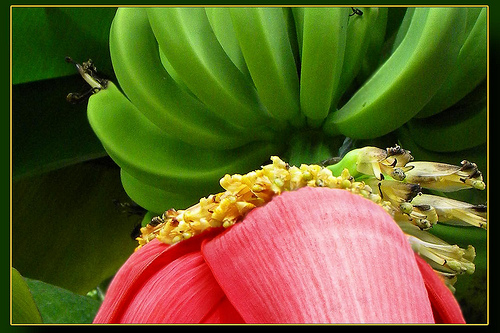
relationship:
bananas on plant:
[60, 8, 482, 277] [12, 2, 491, 329]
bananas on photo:
[60, 8, 482, 277] [1, 1, 497, 331]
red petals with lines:
[160, 194, 427, 327] [288, 247, 377, 322]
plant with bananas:
[95, 190, 462, 325] [301, 4, 333, 116]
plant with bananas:
[95, 190, 462, 325] [240, 6, 298, 118]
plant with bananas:
[95, 190, 462, 325] [159, 4, 249, 120]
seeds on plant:
[149, 149, 393, 239] [61, 7, 487, 322]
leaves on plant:
[92, 186, 468, 322] [66, 141, 485, 322]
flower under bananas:
[172, 144, 433, 221] [106, 24, 446, 159]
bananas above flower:
[66, 8, 488, 294] [90, 145, 488, 324]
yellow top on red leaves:
[133, 152, 397, 239] [199, 185, 433, 326]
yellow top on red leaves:
[133, 152, 397, 239] [414, 250, 471, 322]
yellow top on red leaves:
[133, 152, 397, 239] [91, 222, 246, 322]